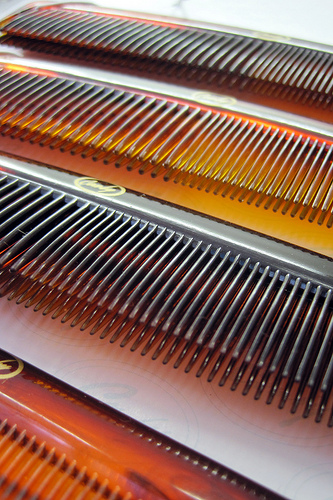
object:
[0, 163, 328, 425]
comb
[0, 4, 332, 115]
comb